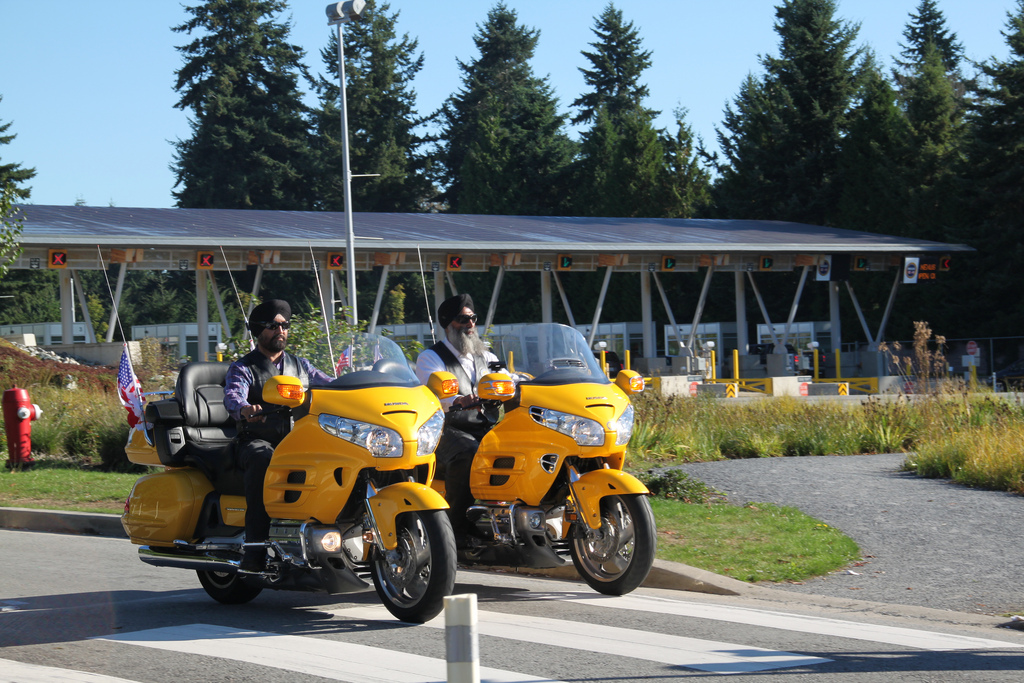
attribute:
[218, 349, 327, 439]
shirt — purple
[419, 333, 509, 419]
shirt — white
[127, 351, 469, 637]
motorcycle — yellow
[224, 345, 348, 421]
shirt — purple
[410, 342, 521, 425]
shirt — white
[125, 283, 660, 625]
motorcycles — yellow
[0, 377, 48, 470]
fire hydrant — red and white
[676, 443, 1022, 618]
path — paved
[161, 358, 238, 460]
seat — black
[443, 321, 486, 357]
beard — grey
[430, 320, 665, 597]
motorcycle — yellow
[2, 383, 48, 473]
hydrant — red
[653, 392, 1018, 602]
grass — tall, green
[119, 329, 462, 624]
motorcycle — yellow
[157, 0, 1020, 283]
trees — green, tall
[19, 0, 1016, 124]
sky — blue, clear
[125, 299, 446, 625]
motorcycle — yellow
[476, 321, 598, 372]
windshield — glass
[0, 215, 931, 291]
covering — tall